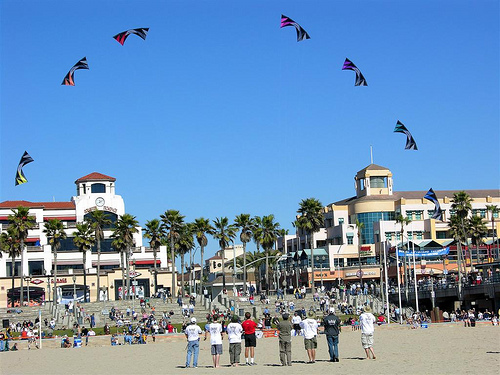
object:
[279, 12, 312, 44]
kite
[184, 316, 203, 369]
man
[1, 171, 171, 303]
building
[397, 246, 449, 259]
banner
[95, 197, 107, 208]
clock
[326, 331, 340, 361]
jeans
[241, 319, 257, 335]
shirt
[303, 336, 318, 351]
shorts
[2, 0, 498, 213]
sky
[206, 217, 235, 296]
tree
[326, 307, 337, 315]
cap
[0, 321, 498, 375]
beach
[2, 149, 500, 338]
city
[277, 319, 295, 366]
outfit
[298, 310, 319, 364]
person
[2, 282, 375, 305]
street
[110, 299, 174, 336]
people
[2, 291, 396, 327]
stairs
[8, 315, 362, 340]
grass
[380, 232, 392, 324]
light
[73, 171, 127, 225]
tower